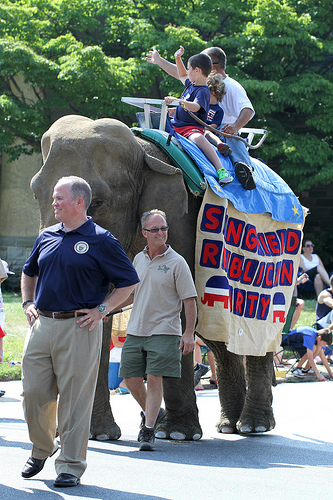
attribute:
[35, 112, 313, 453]
elephant — large, walking, grey, carrying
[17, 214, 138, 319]
polo — blue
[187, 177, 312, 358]
sign — advertising, draped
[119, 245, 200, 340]
polo — beige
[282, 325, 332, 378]
boy — watching, young, bending over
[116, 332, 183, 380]
shorts — green, pair, tan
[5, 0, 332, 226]
trees — green, leafy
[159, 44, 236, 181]
boy — waving, young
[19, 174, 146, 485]
politician — walking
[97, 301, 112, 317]
watch — person's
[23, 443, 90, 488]
shoes — dress shoes, pair, black, dark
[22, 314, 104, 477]
slacks — tan, pair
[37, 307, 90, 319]
belt — leather, brown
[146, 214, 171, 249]
face — person's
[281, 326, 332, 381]
kid — bending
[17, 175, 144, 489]
male — white, walking, posing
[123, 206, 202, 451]
male — white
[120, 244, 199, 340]
shirt — tan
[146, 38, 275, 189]
family — enjoying, young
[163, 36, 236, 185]
male — sitting, young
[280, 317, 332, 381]
male — picking, bent over, young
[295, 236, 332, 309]
woman — sitting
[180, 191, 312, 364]
banner — republican party's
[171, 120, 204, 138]
shorts — red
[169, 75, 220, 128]
tee shirt — blue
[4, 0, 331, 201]
leaves — green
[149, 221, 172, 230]
glasses — tinted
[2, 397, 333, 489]
shadow — elephant's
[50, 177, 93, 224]
face — man's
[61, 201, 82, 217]
splotches — pink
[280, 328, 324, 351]
tee shirt — blue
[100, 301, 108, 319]
wristwatch — man's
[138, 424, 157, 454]
sneaker — lace up, black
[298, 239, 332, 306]
person — wearing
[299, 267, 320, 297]
shorts — dark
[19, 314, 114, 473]
pants — tan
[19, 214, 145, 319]
shirt — blue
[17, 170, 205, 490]
people — walking